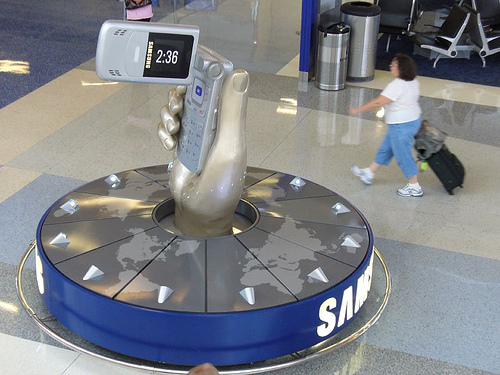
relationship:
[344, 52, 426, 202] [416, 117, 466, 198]
lady pulling backpack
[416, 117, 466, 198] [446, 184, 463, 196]
backpack has wheels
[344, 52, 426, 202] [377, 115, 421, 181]
lady wearing pants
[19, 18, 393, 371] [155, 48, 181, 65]
display shows 2:36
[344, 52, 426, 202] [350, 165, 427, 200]
lady wearing sneakers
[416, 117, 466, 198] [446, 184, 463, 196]
luggage has wheels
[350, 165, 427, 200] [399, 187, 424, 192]
sneakers have stripes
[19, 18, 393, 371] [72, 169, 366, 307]
display has world map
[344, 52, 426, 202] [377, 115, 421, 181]
lady wearing jeans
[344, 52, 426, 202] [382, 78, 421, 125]
lady wearing shirt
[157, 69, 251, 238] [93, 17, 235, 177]
hand holding phone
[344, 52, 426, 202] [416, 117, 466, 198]
lady has luggage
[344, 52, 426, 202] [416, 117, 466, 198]
lady pulling luggage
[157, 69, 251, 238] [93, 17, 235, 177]
hand holding cell phone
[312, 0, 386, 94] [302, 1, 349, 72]
trash receptical by wall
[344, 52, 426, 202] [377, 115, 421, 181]
lady wearing capris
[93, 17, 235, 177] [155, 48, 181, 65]
phone shows time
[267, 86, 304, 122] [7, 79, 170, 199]
reflection on floor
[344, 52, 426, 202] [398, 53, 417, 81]
lady has frizzy hair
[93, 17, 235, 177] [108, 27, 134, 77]
phone has vents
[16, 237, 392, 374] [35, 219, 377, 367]
circle around stand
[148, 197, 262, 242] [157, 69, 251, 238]
circle around hand